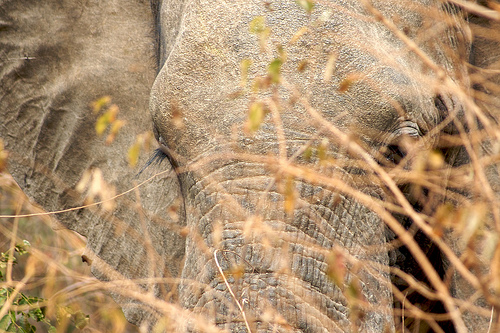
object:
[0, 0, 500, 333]
elephant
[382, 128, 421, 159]
eye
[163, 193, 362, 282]
base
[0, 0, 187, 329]
ear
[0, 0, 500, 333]
head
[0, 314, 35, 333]
leave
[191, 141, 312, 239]
skin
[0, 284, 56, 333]
plant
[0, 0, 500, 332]
grass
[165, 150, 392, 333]
trunk